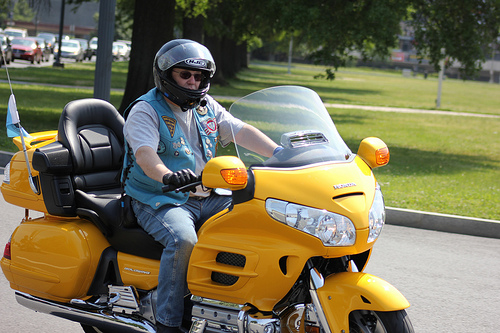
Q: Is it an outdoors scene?
A: Yes, it is outdoors.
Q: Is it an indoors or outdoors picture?
A: It is outdoors.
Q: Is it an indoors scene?
A: No, it is outdoors.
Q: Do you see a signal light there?
A: No, there are no traffic lights.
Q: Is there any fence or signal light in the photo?
A: No, there are no traffic lights or fences.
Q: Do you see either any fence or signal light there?
A: No, there are no traffic lights or fences.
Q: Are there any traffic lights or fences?
A: No, there are no traffic lights or fences.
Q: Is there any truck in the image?
A: No, there are no trucks.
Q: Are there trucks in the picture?
A: No, there are no trucks.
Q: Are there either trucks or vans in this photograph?
A: No, there are no trucks or vans.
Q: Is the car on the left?
A: Yes, the car is on the left of the image.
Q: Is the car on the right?
A: No, the car is on the left of the image.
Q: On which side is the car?
A: The car is on the left of the image.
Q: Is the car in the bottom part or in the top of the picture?
A: The car is in the top of the image.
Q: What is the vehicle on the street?
A: The vehicle is a car.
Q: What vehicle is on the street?
A: The vehicle is a car.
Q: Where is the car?
A: The car is on the street.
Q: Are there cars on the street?
A: Yes, there is a car on the street.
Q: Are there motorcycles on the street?
A: No, there is a car on the street.